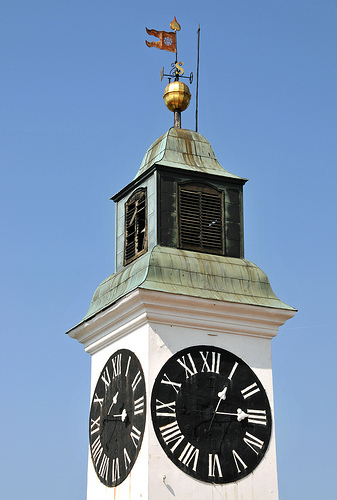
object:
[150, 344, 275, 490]
clock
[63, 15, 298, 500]
tower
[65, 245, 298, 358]
roof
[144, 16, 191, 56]
top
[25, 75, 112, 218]
sky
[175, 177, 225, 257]
shutter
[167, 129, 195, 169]
shingle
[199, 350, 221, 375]
numeral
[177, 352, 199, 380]
number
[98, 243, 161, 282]
rusting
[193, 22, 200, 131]
rod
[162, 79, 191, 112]
ball